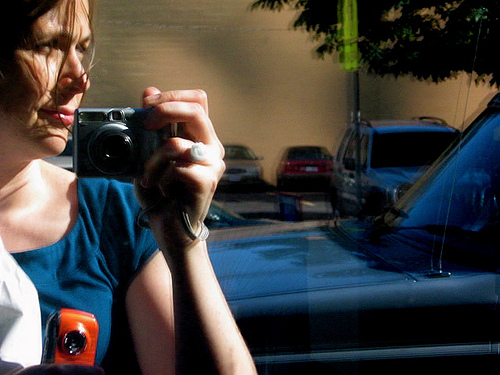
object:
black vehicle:
[203, 90, 500, 375]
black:
[277, 173, 334, 192]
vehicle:
[204, 93, 500, 375]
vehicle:
[330, 115, 463, 222]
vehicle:
[217, 142, 263, 186]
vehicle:
[276, 144, 336, 188]